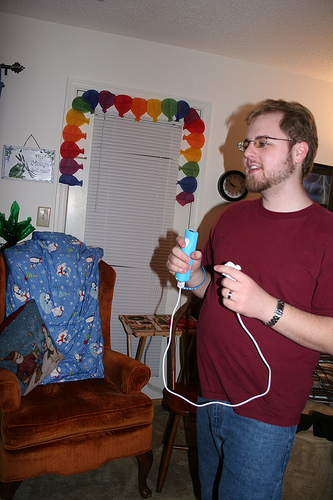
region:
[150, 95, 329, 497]
Man playing video game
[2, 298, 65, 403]
Christmas themed pillow on chair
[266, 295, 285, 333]
Watch on man's wrist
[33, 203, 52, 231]
Electric light switch on wall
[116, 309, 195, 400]
Wooden tray in background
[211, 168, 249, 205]
Round clock on wall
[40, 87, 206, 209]
Colorful paper balloon decoration around window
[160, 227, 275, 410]
Wii video game remote controller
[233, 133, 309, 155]
man with glasses on face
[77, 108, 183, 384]
Blinds covering door window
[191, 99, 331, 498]
Man standing in room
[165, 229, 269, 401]
Game remote in man's hands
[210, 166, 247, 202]
Circular clock on wall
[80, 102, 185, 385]
Mini blinds covering window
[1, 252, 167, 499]
Chair with orange fabric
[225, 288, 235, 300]
Ring on man's finger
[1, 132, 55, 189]
Sign hanging on the wall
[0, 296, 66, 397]
Christmas pillow on chair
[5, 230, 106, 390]
Blanket laying on back of chair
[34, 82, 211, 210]
Multiple papers on the door frame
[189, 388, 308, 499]
His jeans are dark blue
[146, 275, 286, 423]
White wire from the wii remote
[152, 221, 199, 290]
This remote has a blue cover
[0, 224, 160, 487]
Chair is light brown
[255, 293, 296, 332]
Wrist watch is silver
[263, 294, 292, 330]
This is made of metal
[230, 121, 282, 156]
Looking at the TV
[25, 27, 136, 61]
Paint is white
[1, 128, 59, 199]
A sign on the wall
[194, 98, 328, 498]
man playing video game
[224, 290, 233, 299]
ring on man's finger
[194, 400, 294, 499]
blue jeans of man playing video game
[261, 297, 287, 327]
watch band on man's wrist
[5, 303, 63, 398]
christmas themed throw pillow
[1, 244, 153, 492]
cushioned brown chair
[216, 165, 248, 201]
clock with black frame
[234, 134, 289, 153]
eye glasses of man playing video game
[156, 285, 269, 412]
white cord of video game controllers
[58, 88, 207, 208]
balloon banner around window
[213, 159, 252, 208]
black framed black and white clock on wall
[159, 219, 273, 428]
blue and white game controller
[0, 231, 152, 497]
red stuffed chair with wooden legs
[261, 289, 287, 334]
metal watch on wrist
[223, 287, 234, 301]
metal ring on finger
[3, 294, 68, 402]
holiday themed throw pillow on chair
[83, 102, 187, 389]
pair of white blinds covering window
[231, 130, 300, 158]
pair of glasses on man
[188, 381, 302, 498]
pair of blue jeans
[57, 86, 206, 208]
multi colored string of baloon shaped cut outs partially strung around a window